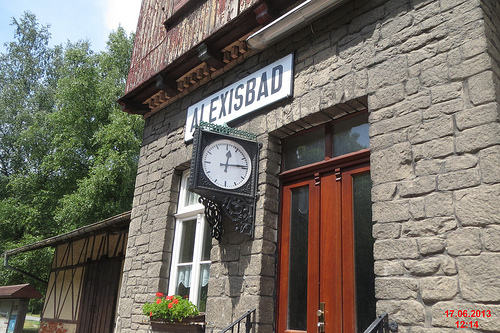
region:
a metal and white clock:
[180, 121, 271, 242]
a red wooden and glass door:
[264, 85, 401, 330]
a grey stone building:
[112, 61, 499, 330]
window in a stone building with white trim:
[153, 156, 227, 331]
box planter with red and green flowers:
[133, 285, 215, 330]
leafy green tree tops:
[0, 6, 141, 265]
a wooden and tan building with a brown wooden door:
[3, 204, 128, 331]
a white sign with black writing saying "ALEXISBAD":
[176, 42, 311, 147]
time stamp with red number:
[438, 288, 495, 331]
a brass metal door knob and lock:
[311, 299, 331, 331]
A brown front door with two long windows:
[276, 150, 374, 332]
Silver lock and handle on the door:
[305, 298, 330, 330]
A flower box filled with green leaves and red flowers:
[136, 286, 206, 331]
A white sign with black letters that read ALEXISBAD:
[183, 53, 301, 138]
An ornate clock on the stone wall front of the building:
[185, 121, 272, 239]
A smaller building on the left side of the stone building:
[2, 200, 131, 332]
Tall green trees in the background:
[1, 9, 134, 227]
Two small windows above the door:
[271, 104, 378, 172]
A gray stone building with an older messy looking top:
[105, 0, 498, 331]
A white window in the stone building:
[163, 165, 211, 312]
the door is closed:
[271, 176, 391, 328]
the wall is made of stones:
[385, 90, 477, 302]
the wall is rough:
[380, 112, 470, 286]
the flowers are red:
[137, 290, 212, 317]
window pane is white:
[157, 167, 224, 331]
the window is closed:
[161, 163, 224, 330]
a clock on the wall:
[163, 100, 260, 259]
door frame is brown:
[269, 158, 351, 325]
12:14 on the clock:
[191, 141, 268, 212]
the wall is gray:
[386, 81, 479, 241]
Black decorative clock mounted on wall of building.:
[182, 118, 266, 241]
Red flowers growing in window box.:
[136, 287, 209, 330]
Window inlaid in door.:
[284, 182, 316, 332]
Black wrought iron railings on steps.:
[215, 303, 258, 331]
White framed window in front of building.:
[161, 203, 222, 313]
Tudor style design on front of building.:
[40, 245, 87, 319]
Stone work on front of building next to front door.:
[376, 132, 493, 290]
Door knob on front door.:
[312, 296, 330, 331]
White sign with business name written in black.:
[178, 43, 298, 138]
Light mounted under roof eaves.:
[236, 3, 388, 51]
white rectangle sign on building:
[176, 46, 301, 146]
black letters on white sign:
[250, 61, 282, 96]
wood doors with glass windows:
[272, 134, 372, 331]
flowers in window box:
[145, 284, 211, 326]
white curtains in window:
[168, 241, 211, 291]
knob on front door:
[308, 301, 328, 331]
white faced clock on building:
[199, 134, 259, 195]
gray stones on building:
[414, 118, 480, 235]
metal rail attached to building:
[227, 306, 262, 330]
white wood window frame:
[172, 209, 204, 239]